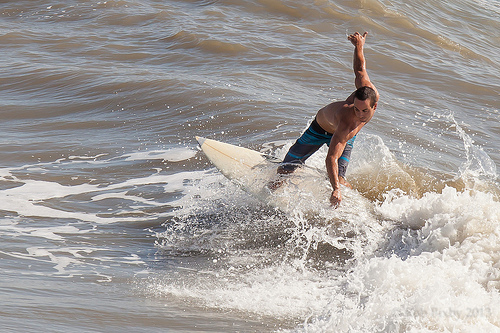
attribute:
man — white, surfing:
[263, 30, 381, 215]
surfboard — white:
[190, 134, 377, 256]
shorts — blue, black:
[277, 117, 359, 178]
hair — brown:
[351, 85, 378, 108]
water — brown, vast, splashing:
[2, 2, 498, 330]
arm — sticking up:
[347, 28, 384, 94]